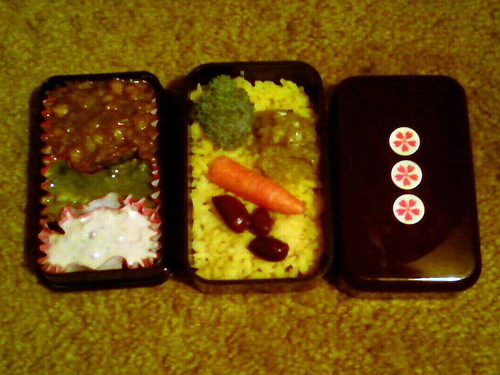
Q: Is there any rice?
A: Yes, there is rice.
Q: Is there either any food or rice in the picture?
A: Yes, there is rice.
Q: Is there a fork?
A: No, there are no forks.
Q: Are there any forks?
A: No, there are no forks.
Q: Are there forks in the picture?
A: No, there are no forks.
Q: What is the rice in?
A: The rice is in the bowl.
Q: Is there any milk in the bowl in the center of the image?
A: No, there is rice in the bowl.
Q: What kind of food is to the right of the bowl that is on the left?
A: The food is rice.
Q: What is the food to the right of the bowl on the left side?
A: The food is rice.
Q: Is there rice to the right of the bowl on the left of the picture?
A: Yes, there is rice to the right of the bowl.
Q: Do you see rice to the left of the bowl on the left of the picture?
A: No, the rice is to the right of the bowl.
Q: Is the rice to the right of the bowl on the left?
A: Yes, the rice is to the right of the bowl.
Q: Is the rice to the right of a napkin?
A: No, the rice is to the right of the bowl.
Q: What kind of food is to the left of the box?
A: The food is rice.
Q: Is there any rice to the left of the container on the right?
A: Yes, there is rice to the left of the box.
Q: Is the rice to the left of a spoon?
A: No, the rice is to the left of a box.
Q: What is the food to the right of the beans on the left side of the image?
A: The food is rice.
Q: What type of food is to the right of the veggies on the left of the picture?
A: The food is rice.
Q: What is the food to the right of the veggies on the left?
A: The food is rice.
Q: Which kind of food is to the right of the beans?
A: The food is rice.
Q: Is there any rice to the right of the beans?
A: Yes, there is rice to the right of the beans.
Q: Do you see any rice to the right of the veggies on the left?
A: Yes, there is rice to the right of the beans.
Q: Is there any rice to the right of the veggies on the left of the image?
A: Yes, there is rice to the right of the beans.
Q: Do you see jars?
A: No, there are no jars.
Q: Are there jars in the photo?
A: No, there are no jars.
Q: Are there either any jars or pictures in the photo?
A: No, there are no jars or pictures.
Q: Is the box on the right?
A: Yes, the box is on the right of the image.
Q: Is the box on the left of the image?
A: No, the box is on the right of the image.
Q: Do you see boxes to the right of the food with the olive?
A: Yes, there is a box to the right of the rice.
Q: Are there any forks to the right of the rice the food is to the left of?
A: No, there is a box to the right of the rice.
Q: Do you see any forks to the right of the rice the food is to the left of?
A: No, there is a box to the right of the rice.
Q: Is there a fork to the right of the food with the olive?
A: No, there is a box to the right of the rice.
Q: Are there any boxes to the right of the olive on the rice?
A: Yes, there is a box to the right of the olive.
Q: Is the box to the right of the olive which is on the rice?
A: Yes, the box is to the right of the olive.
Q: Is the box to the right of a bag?
A: No, the box is to the right of the olive.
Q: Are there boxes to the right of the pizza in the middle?
A: Yes, there is a box to the right of the pizza.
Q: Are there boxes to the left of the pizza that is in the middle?
A: No, the box is to the right of the pizza.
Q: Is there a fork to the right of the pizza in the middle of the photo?
A: No, there is a box to the right of the pizza.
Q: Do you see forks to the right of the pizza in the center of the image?
A: No, there is a box to the right of the pizza.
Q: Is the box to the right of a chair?
A: No, the box is to the right of the pizza.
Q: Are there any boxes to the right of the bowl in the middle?
A: Yes, there is a box to the right of the bowl.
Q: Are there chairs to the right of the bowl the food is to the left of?
A: No, there is a box to the right of the bowl.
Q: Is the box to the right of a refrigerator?
A: No, the box is to the right of the bowl.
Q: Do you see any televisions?
A: No, there are no televisions.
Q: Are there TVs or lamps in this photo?
A: No, there are no TVs or lamps.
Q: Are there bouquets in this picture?
A: No, there are no bouquets.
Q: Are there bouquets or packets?
A: No, there are no bouquets or packets.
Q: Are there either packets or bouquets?
A: No, there are no bouquets or packets.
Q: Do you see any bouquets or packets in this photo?
A: No, there are no bouquets or packets.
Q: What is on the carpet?
A: The trays are on the carpet.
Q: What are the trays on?
A: The trays are on the carpet.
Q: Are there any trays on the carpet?
A: Yes, there are trays on the carpet.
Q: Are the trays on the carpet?
A: Yes, the trays are on the carpet.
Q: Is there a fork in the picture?
A: No, there are no forks.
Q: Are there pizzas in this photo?
A: Yes, there is a pizza.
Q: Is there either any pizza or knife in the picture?
A: Yes, there is a pizza.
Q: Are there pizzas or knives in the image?
A: Yes, there is a pizza.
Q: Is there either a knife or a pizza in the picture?
A: Yes, there is a pizza.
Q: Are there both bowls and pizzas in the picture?
A: Yes, there are both a pizza and a bowl.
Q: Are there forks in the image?
A: No, there are no forks.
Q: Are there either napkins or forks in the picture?
A: No, there are no forks or napkins.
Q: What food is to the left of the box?
A: The food is a pizza.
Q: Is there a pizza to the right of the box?
A: No, the pizza is to the left of the box.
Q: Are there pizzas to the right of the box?
A: No, the pizza is to the left of the box.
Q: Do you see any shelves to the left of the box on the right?
A: No, there is a pizza to the left of the box.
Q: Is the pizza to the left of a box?
A: Yes, the pizza is to the left of a box.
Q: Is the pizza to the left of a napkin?
A: No, the pizza is to the left of a box.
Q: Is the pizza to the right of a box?
A: No, the pizza is to the left of a box.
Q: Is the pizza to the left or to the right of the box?
A: The pizza is to the left of the box.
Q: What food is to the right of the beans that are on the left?
A: The food is a pizza.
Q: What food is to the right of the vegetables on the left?
A: The food is a pizza.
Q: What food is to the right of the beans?
A: The food is a pizza.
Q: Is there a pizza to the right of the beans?
A: Yes, there is a pizza to the right of the beans.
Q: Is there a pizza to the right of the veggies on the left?
A: Yes, there is a pizza to the right of the beans.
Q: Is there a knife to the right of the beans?
A: No, there is a pizza to the right of the beans.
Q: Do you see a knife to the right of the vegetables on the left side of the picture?
A: No, there is a pizza to the right of the beans.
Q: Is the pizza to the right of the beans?
A: Yes, the pizza is to the right of the beans.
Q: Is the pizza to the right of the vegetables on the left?
A: Yes, the pizza is to the right of the beans.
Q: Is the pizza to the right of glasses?
A: No, the pizza is to the right of the beans.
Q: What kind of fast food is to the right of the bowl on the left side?
A: The food is a pizza.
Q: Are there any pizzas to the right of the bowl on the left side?
A: Yes, there is a pizza to the right of the bowl.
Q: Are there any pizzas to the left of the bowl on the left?
A: No, the pizza is to the right of the bowl.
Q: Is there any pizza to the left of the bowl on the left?
A: No, the pizza is to the right of the bowl.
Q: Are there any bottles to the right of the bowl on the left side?
A: No, there is a pizza to the right of the bowl.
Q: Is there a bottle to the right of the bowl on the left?
A: No, there is a pizza to the right of the bowl.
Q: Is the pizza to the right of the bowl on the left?
A: Yes, the pizza is to the right of the bowl.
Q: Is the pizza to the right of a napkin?
A: No, the pizza is to the right of the bowl.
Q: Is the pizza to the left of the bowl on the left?
A: No, the pizza is to the right of the bowl.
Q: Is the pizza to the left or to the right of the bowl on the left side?
A: The pizza is to the right of the bowl.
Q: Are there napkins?
A: No, there are no napkins.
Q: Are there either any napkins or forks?
A: No, there are no napkins or forks.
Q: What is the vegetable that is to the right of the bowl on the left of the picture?
A: The vegetable is an olive.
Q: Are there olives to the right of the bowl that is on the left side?
A: Yes, there is an olive to the right of the bowl.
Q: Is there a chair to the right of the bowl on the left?
A: No, there is an olive to the right of the bowl.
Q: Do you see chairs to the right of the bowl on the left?
A: No, there is an olive to the right of the bowl.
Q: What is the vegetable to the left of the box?
A: The vegetable is an olive.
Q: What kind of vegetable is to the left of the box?
A: The vegetable is an olive.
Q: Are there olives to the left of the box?
A: Yes, there is an olive to the left of the box.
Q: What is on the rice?
A: The olive is on the rice.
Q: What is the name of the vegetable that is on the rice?
A: The vegetable is an olive.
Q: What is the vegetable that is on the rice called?
A: The vegetable is an olive.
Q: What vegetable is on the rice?
A: The vegetable is an olive.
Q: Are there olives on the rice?
A: Yes, there is an olive on the rice.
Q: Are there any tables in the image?
A: Yes, there is a table.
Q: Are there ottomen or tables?
A: Yes, there is a table.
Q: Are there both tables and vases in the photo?
A: No, there is a table but no vases.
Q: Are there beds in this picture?
A: No, there are no beds.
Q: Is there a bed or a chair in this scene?
A: No, there are no beds or chairs.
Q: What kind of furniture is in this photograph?
A: The furniture is a table.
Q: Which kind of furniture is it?
A: The piece of furniture is a table.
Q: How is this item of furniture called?
A: This is a table.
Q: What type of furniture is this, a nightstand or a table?
A: This is a table.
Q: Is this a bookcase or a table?
A: This is a table.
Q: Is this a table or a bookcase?
A: This is a table.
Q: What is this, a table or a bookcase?
A: This is a table.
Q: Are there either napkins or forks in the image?
A: No, there are no forks or napkins.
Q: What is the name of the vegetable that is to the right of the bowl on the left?
A: The vegetable is an olive.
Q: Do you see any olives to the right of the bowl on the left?
A: Yes, there is an olive to the right of the bowl.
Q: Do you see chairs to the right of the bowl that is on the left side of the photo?
A: No, there is an olive to the right of the bowl.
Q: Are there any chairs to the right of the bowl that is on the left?
A: No, there is an olive to the right of the bowl.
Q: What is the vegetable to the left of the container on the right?
A: The vegetable is an olive.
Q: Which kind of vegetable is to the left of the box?
A: The vegetable is an olive.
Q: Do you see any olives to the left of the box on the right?
A: Yes, there is an olive to the left of the box.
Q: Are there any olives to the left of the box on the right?
A: Yes, there is an olive to the left of the box.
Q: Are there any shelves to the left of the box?
A: No, there is an olive to the left of the box.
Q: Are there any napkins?
A: No, there are no napkins.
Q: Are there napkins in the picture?
A: No, there are no napkins.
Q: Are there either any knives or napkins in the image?
A: No, there are no napkins or knives.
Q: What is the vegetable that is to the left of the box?
A: The vegetable is an olive.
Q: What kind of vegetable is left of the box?
A: The vegetable is an olive.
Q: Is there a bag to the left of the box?
A: No, there is an olive to the left of the box.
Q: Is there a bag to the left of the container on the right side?
A: No, there is an olive to the left of the box.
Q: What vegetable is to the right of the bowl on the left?
A: The vegetable is an olive.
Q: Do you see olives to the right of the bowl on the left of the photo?
A: Yes, there is an olive to the right of the bowl.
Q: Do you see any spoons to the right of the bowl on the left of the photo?
A: No, there is an olive to the right of the bowl.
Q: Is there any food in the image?
A: Yes, there is food.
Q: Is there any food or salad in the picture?
A: Yes, there is food.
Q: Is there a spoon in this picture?
A: No, there are no spoons.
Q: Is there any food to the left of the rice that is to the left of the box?
A: Yes, there is food to the left of the rice.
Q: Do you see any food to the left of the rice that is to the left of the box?
A: Yes, there is food to the left of the rice.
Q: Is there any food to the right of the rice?
A: No, the food is to the left of the rice.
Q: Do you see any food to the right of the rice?
A: No, the food is to the left of the rice.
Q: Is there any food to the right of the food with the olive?
A: No, the food is to the left of the rice.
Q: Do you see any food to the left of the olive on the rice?
A: Yes, there is food to the left of the olive.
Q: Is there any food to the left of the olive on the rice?
A: Yes, there is food to the left of the olive.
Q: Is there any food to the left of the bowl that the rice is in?
A: Yes, there is food to the left of the bowl.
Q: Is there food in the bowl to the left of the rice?
A: Yes, there is food in the bowl.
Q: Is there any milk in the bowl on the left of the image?
A: No, there is food in the bowl.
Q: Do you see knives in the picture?
A: No, there are no knives.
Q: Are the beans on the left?
A: Yes, the beans are on the left of the image.